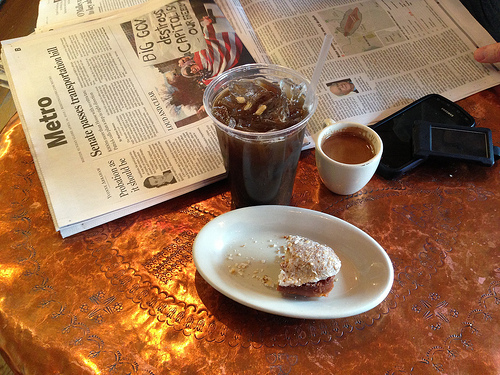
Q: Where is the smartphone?
A: On the table.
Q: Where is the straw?
A: In the cup.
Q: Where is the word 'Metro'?
A: On the newspaper.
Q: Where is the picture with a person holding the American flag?
A: The newspaper.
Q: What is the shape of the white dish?
A: Oval.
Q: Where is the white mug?
A: On the table.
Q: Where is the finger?
A: To the right.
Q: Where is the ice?
A: In the plastic cup.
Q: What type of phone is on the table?
A: A smartphone.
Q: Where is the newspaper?
A: On the table.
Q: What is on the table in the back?
A: Newspaper.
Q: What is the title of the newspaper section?
A: Metro.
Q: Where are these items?
A: On a table.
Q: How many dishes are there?
A: One.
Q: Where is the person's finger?
A: On the right.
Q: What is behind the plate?
A: Cup of soda.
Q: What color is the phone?
A: Black.